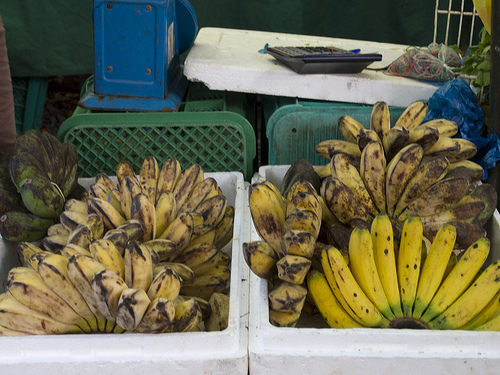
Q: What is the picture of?
A: Bananas.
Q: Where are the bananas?
A: Inside white crates.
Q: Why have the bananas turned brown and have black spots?
A: Most of them are overripe except one bunch.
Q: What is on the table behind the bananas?
A: A calculator.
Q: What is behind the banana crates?
A: A few green plastic crates and bins.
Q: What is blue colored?
A: A weighing scale.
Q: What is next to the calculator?
A: Packet of rubber bands.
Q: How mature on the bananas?
A: Ripe.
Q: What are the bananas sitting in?
A: Crate.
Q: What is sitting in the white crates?
A: Bananas.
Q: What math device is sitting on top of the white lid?
A: A calculator.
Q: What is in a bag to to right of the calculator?
A: Rubber bands.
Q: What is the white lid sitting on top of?
A: A green crate.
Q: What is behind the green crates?
A: A green tarp.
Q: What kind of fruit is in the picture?
A: Bananas.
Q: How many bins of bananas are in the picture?
A: Two.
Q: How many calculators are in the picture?
A: One.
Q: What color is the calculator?
A: Black.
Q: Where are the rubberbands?
A: In plastic bag.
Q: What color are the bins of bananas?
A: White.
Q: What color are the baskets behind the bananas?
A: Green.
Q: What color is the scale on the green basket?
A: Blue.